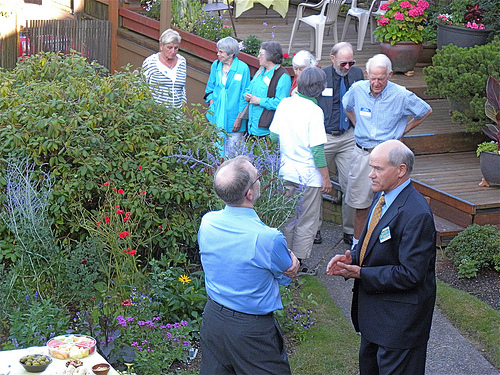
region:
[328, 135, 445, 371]
A man in a navy blue suit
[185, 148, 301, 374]
A man in a light blue shirt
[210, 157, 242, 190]
A bald spot on a man's head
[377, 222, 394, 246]
A badge attached to the suit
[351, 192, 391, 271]
A gold neck tie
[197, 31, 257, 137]
A woman in a blue shirt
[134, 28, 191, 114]
A woman in a striped shirt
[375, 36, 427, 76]
A large flower pot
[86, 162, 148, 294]
A group of red flowers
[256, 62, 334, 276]
A person in a white shirt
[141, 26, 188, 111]
A grey haired woman in a blue and white striped shirt.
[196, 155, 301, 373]
A balding man in a blue shirt with his arms folded.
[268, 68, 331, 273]
The back of a woman in a white and green shirt on.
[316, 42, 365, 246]
A man in khaki pants with dark shades on and a name tag.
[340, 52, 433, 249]
A white haired old man with a blue shirt on and hands on his back.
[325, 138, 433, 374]
A balding man in a black suit with his hands out talking to a man in blue.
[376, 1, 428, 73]
A large planter with big pink flowers inside.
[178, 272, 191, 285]
A yellow lazy susan flower to the left of a man in blue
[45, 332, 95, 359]
A fruit assortment in a plastic clear container.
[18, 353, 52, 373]
A small black bowl of olives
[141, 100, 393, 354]
This is a group of people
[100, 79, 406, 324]
The people are elderly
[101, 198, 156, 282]
These are red flowers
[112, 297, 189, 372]
These are purple flowers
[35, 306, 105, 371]
This is good food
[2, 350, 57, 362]
These are olives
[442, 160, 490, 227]
This is a wooden deck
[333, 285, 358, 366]
This is a paved path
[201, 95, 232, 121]
This is a blue shirt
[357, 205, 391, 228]
This is a yellow tie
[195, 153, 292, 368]
back view of balding man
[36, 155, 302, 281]
man standing among various colored flowers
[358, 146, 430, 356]
balding man in suit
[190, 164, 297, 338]
back view of man in light blue shirt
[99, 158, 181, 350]
group of purple and red wild flowers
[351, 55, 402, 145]
older man in light blue shirt with name tag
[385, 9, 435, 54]
potted pink flowers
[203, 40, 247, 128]
older woman wearing turquoise colored jacket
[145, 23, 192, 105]
older woman wearing striped shirt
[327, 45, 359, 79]
older man wearing dark sunglasses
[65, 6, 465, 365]
group of senior citizens in a garden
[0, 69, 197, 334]
flowers and green shrubs in a garden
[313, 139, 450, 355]
bald man wearing a dark gray suit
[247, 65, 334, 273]
woman wearing dark tan pants and a white shirt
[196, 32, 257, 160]
woman wearing ten pants and a blue jacket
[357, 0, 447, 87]
potted pink flowered plant on a deck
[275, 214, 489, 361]
gray paved pathway in the garden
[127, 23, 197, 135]
woman with striped shirt and short gray hair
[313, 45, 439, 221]
man with tan shorts and light blue shirt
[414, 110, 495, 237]
wooden decking with potted plants